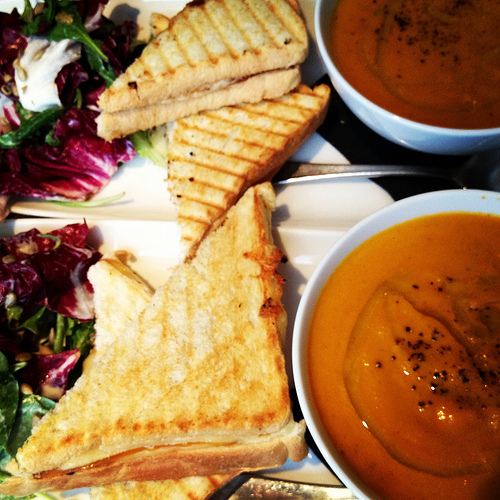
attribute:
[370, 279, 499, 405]
condiment — black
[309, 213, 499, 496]
soup — orange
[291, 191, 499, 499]
bowl — white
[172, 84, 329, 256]
bread — toasted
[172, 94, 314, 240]
lines — grilled marks, white, orange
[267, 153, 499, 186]
spoon — silver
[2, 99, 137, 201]
lettuce — red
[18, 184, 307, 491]
sandwich — grilled, in triangles, toasted cheese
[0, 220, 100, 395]
vegetable — purple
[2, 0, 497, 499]
plate — white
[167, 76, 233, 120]
cheese — melted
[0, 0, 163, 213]
salad — green, purple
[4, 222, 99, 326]
cabbage — red